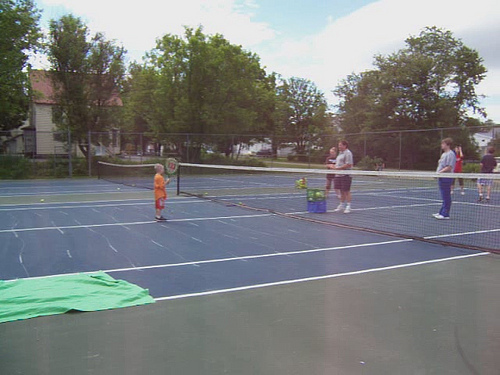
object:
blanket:
[0, 270, 154, 322]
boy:
[154, 163, 170, 220]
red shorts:
[156, 198, 165, 209]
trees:
[332, 25, 490, 173]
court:
[1, 183, 499, 331]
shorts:
[334, 174, 352, 191]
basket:
[307, 189, 325, 202]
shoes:
[432, 213, 449, 220]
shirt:
[154, 175, 166, 200]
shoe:
[334, 205, 344, 211]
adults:
[334, 141, 353, 213]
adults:
[433, 137, 453, 220]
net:
[97, 161, 154, 189]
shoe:
[154, 216, 168, 221]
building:
[2, 70, 122, 159]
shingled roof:
[30, 70, 122, 106]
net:
[178, 163, 500, 255]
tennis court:
[0, 173, 500, 375]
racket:
[164, 158, 179, 179]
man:
[432, 137, 454, 221]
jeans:
[439, 177, 453, 216]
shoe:
[343, 207, 351, 214]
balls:
[308, 191, 323, 200]